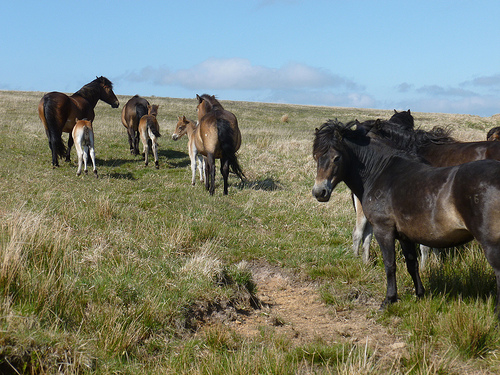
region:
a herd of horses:
[37, 76, 498, 311]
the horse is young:
[72, 118, 99, 175]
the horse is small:
[172, 115, 205, 187]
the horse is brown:
[40, 76, 120, 167]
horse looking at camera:
[312, 119, 349, 200]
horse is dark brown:
[311, 119, 498, 310]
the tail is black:
[218, 120, 246, 182]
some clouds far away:
[118, 58, 498, 115]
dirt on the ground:
[227, 272, 407, 357]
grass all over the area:
[1, 92, 498, 374]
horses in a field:
[49, 29, 316, 268]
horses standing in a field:
[38, 34, 284, 231]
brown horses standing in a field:
[23, 43, 354, 241]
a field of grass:
[132, 169, 386, 359]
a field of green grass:
[69, 191, 260, 372]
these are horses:
[27, 49, 499, 342]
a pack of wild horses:
[15, 47, 497, 340]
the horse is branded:
[440, 182, 497, 212]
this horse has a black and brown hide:
[280, 105, 498, 315]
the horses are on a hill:
[32, 46, 498, 353]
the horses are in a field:
[5, 45, 497, 345]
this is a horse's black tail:
[214, 116, 249, 187]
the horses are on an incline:
[25, 60, 496, 344]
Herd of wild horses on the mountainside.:
[19, 62, 498, 318]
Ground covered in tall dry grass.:
[3, 196, 178, 362]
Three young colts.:
[70, 99, 205, 191]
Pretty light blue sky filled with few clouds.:
[18, 7, 495, 78]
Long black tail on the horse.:
[211, 117, 251, 184]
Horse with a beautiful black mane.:
[304, 116, 401, 208]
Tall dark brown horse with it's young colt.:
[20, 69, 121, 186]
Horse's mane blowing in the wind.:
[382, 117, 457, 149]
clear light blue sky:
[11, 23, 121, 53]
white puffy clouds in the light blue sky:
[152, 54, 371, 95]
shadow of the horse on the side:
[255, 173, 280, 193]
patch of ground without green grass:
[263, 275, 319, 329]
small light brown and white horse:
[71, 117, 103, 177]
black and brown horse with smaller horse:
[36, 75, 121, 170]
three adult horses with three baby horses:
[39, 70, 250, 197]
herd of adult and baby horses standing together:
[304, 108, 496, 308]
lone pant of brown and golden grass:
[278, 113, 294, 125]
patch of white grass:
[186, 243, 218, 285]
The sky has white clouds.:
[131, 45, 352, 105]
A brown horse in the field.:
[34, 80, 121, 160]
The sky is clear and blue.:
[83, 15, 434, 70]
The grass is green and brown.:
[41, 198, 193, 320]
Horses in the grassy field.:
[33, 77, 248, 215]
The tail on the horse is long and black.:
[40, 95, 65, 151]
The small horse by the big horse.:
[65, 110, 103, 180]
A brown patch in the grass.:
[170, 265, 330, 320]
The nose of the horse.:
[307, 175, 337, 209]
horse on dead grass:
[38, 74, 127, 180]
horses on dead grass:
[32, 63, 269, 206]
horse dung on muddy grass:
[163, 249, 295, 339]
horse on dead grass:
[300, 108, 498, 327]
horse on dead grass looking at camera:
[289, 97, 496, 332]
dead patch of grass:
[205, 234, 404, 371]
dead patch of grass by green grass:
[140, 206, 425, 371]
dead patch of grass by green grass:
[249, 117, 300, 169]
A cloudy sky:
[0, 33, 492, 115]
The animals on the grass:
[37, 68, 494, 340]